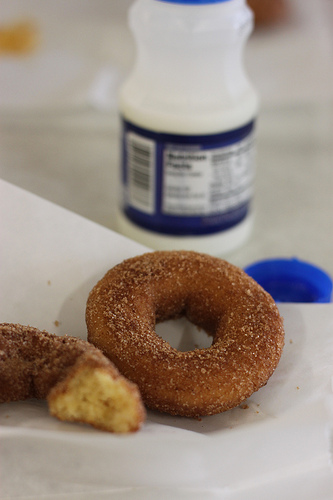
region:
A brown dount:
[78, 239, 290, 435]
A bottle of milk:
[96, 0, 287, 256]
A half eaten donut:
[1, 316, 159, 440]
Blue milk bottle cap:
[228, 235, 332, 348]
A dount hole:
[128, 275, 237, 368]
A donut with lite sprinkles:
[88, 242, 283, 415]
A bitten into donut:
[50, 359, 149, 437]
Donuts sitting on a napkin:
[2, 216, 282, 482]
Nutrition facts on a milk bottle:
[100, 114, 271, 236]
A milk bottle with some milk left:
[91, 35, 273, 251]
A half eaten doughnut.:
[18, 316, 136, 441]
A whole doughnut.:
[88, 253, 275, 399]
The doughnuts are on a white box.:
[10, 206, 327, 498]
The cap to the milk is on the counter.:
[247, 249, 331, 316]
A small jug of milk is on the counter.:
[113, 7, 295, 247]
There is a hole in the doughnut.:
[140, 291, 247, 377]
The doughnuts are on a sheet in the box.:
[18, 406, 209, 479]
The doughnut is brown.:
[110, 306, 163, 378]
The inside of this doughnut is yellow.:
[63, 372, 143, 426]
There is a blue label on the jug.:
[122, 129, 254, 213]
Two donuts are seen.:
[12, 277, 240, 413]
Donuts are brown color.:
[127, 335, 197, 393]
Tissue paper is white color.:
[177, 438, 279, 487]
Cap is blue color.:
[277, 243, 316, 290]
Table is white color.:
[277, 166, 327, 225]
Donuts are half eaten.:
[40, 344, 140, 418]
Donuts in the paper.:
[104, 362, 227, 470]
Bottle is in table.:
[186, 176, 306, 242]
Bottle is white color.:
[160, 83, 227, 135]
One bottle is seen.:
[103, 85, 303, 202]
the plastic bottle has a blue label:
[121, 0, 258, 254]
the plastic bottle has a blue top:
[120, 0, 253, 105]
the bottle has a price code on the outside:
[122, 128, 150, 209]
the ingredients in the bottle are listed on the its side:
[158, 130, 247, 212]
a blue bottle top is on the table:
[241, 247, 328, 301]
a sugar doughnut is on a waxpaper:
[84, 248, 283, 413]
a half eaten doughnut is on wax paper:
[0, 321, 141, 427]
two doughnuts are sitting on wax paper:
[0, 246, 282, 430]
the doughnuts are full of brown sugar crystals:
[0, 248, 282, 428]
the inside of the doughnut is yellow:
[45, 348, 147, 437]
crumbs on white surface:
[232, 396, 271, 413]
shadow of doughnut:
[172, 409, 292, 454]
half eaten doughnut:
[50, 364, 158, 445]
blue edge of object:
[240, 250, 330, 284]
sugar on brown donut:
[151, 346, 226, 374]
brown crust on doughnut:
[173, 405, 211, 429]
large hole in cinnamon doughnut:
[145, 288, 228, 373]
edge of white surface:
[6, 192, 88, 222]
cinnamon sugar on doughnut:
[102, 307, 217, 408]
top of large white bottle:
[118, 0, 259, 9]